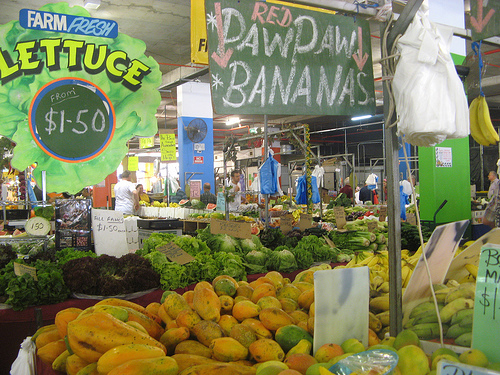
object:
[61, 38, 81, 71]
letter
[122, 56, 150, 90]
letter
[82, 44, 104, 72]
letter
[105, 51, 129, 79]
letter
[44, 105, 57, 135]
dollar sign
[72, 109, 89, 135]
number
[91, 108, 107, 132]
number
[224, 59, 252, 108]
letter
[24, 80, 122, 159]
price display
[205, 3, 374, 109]
sign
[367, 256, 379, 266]
bananas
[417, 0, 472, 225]
pillar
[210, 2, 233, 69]
arrow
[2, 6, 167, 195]
pillar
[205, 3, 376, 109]
banner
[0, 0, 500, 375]
market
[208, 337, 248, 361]
squash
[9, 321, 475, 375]
bin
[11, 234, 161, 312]
bin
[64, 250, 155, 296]
lettuce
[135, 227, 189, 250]
table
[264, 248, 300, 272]
greens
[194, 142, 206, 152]
sign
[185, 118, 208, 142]
fan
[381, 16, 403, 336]
pole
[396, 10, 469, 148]
bags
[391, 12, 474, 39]
stand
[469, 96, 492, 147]
banana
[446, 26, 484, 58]
stand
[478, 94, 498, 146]
banana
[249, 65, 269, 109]
white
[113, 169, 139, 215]
people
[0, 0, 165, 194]
sign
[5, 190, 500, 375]
different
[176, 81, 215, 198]
pillar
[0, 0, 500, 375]
background